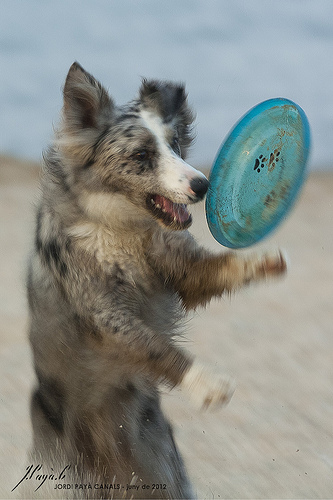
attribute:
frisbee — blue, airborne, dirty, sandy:
[200, 93, 314, 250]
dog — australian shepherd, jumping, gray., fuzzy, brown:
[26, 58, 290, 500]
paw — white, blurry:
[201, 245, 297, 290]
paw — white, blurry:
[179, 352, 238, 414]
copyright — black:
[12, 458, 170, 496]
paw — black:
[267, 145, 283, 174]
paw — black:
[252, 151, 268, 180]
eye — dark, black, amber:
[169, 132, 181, 152]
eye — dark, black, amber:
[128, 148, 155, 165]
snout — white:
[147, 148, 207, 202]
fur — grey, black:
[22, 60, 286, 498]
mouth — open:
[142, 186, 199, 227]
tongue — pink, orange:
[155, 193, 188, 222]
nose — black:
[189, 176, 212, 198]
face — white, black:
[105, 117, 209, 228]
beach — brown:
[1, 145, 333, 499]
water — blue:
[2, 1, 332, 179]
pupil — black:
[137, 151, 142, 157]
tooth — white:
[172, 214, 178, 221]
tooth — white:
[162, 206, 167, 214]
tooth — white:
[156, 203, 161, 211]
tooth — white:
[149, 197, 154, 205]